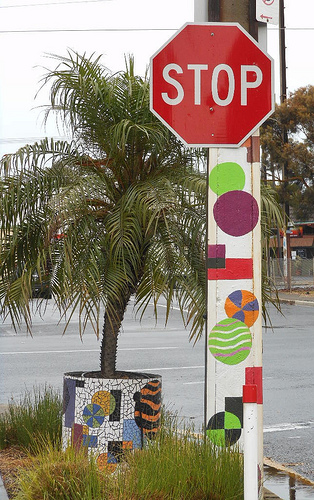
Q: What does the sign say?
A: Stop.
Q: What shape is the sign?
A: Octagon.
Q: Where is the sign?
A: Street pole.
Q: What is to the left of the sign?
A: Potted plant.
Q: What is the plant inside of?
A: Pot.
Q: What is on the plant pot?
A: Colorful geometric designs.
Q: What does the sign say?
A: Stop.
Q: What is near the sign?
A: A tree.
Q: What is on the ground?
A: Grass.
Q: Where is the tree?
A: In a big pot.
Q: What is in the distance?
A: A building.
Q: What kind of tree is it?
A: Palm.